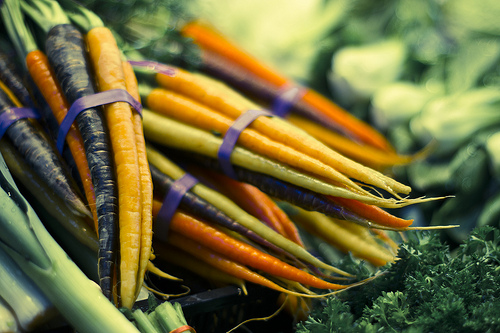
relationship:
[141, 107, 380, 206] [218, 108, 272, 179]
carrot in band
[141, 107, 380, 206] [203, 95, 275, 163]
carrot in band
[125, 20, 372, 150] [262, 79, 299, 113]
carror in band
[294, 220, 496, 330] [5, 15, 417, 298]
parsley near carrots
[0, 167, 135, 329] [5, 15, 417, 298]
vegetable stalk near carrots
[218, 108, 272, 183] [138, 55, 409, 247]
band holding carrots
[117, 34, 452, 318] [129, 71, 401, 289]
root extending from carrot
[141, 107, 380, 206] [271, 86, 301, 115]
carrot holding rubber band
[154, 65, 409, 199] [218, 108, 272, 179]
carrot holding band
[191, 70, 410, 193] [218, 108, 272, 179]
carrot holding band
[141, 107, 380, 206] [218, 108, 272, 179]
carrot holding band